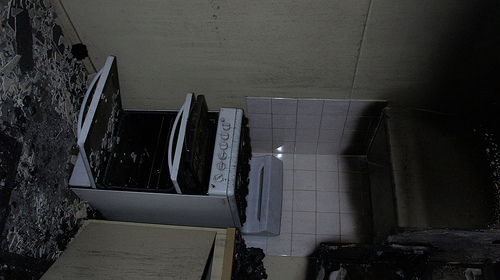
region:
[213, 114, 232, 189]
knobs on the stove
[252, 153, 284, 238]
door of the oven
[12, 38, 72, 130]
burned wall behind oven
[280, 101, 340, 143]
white tiled walls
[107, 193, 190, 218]
side of the stove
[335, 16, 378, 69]
line on the wall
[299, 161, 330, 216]
lines on the floor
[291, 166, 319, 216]
squares on the floor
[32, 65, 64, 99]
white plaster on the wall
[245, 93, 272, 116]
a white tile on the wall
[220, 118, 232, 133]
a white knob on the oven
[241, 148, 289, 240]
a white oven top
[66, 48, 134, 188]
the door of the oven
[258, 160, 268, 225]
a vent on the oven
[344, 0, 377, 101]
a crack in the wall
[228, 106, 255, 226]
the burners on the stove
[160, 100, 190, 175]
the handle of an oven door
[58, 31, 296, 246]
a white oven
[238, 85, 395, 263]
a white tile wall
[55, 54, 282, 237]
White stove leaning against tile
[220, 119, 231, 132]
White knob on white stove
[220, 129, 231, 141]
White knob on white stove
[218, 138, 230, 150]
White knob on white stove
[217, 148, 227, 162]
White knob on white stove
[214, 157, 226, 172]
White knob on white stove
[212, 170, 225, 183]
White knob on white stove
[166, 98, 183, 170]
White door handle on white stove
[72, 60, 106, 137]
White door handle on white stove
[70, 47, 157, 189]
Oven door is opened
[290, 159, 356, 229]
The tile on the floor are white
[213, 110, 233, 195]
The knobs on the stove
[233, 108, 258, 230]
The eyes on the stove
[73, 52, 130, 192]
The door of the oven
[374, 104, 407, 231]
The edge of the wall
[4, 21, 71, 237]
The floor has broken tiles on it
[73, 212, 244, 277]
The cabinet is the color beige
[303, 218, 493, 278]
The wall has been burnt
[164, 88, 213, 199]
The pull out drawer on the stove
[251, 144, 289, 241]
The top of the stove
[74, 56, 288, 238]
White stove with open doors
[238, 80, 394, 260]
White tile wall in kitchen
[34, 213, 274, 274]
Old brown cabinet with open door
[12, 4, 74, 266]
Floor littered with black and gray pieces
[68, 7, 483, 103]
Tan wall stained with grime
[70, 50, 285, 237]
White stove with six dials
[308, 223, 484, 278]
Black burned out cabinet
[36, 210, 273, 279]
Lower cabinet with soot steaks on door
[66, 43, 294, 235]
Oven with black burners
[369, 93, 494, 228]
Black and gray sooty wall